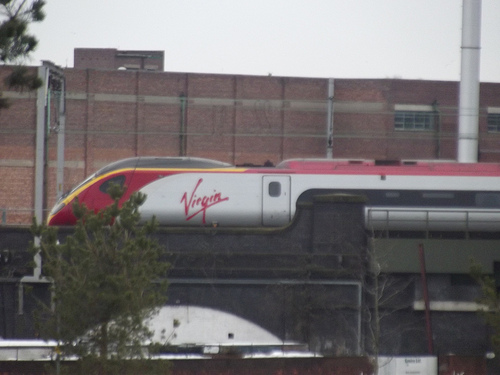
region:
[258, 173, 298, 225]
door on the train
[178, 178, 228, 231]
logo on the train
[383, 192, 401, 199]
window on the train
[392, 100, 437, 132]
window on the building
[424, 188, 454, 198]
window on the train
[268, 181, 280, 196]
window on the train door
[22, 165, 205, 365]
tree next to the train tracks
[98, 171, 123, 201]
window on the train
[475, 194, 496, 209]
window on the train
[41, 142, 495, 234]
train on the train track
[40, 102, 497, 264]
this is a train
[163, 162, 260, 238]
red writing on the train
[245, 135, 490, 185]
red top of train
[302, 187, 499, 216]
row of windows on train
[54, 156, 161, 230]
red nose of train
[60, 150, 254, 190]
yellow trim on train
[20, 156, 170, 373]
this is a tree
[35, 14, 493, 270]
building behind the train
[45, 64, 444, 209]
the building is brick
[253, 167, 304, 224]
door on the side of the train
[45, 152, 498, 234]
a red and silver train engine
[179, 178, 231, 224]
red Virgin corporate logo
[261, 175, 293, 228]
a train entry exit door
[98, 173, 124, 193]
a train cockpit window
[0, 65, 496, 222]
a red brick building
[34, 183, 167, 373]
a small green tree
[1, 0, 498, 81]
an overcast white sky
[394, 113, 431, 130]
a multi paned building window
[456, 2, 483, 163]
a tall metal pole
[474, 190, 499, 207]
a train passenger window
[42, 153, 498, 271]
virgin train on track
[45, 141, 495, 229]
red and grey train on track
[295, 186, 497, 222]
black strip of windows in train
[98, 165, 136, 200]
small window on front of train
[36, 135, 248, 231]
thin yellow strip on train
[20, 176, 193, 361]
many needles on evergreen tree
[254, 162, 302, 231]
cabin door closed on train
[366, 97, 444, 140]
window on top floor of brick building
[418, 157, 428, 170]
part of a train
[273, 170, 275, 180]
part of a building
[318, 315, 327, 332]
part of a fence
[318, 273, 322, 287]
edge of a train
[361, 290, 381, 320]
part of a bracnh